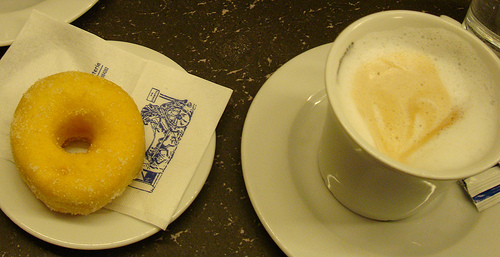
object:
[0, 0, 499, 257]
table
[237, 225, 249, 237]
spots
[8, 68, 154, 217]
donut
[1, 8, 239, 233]
napkin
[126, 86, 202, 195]
drawing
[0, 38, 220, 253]
plate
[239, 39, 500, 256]
plate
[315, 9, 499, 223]
mug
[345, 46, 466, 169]
coffee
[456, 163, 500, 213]
bag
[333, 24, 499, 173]
foam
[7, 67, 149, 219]
sugar